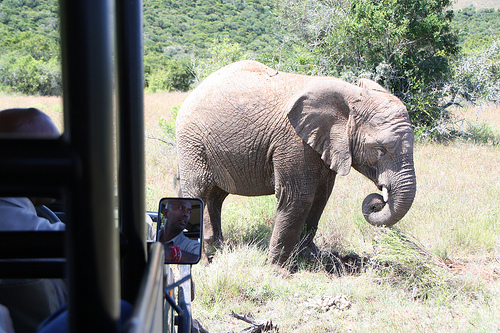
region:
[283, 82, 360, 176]
the ear of an elephant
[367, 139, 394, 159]
the eye of an elephant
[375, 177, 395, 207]
the tusk of an elephant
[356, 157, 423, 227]
the trunk of an elephant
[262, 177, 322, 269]
the leg of an elephant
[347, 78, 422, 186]
the head of an elephant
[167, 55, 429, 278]
a large gray elephant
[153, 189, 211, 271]
a side view mirror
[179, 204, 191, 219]
the nose of a person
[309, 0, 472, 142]
a green tree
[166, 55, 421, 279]
a gray elephant on the ground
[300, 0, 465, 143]
a large green tree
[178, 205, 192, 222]
the nose of a man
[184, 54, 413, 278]
An elephant in the grass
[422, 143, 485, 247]
Tall green grass behind the elephant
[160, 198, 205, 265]
Mirror on the vehicle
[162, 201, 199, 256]
Concerned man's reflection in the mirror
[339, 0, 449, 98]
A bushy tree is visible behind the elephant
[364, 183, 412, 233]
A curled elephant's trunk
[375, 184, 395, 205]
The elephant's tusks are short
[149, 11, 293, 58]
Many trees visible in the background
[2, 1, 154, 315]
A vehicle in front of the elephant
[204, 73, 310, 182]
The elephant's skin is wrinkled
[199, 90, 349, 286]
an elephant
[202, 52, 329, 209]
an elephant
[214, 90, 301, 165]
an elephant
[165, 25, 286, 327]
an elephant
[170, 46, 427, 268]
The elephant is grey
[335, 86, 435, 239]
The elephant has white tusks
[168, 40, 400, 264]
The elephant is standing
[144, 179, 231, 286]
Man in the mirror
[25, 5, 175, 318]
Black bars of the vehicle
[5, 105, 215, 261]
Man is driving the vehicle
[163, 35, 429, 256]
Elephant is in a grassy clearing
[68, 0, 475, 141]
Dense green foliage behind elephant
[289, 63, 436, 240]
The elephant's trunk is curled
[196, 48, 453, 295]
The elephant is eating the bush